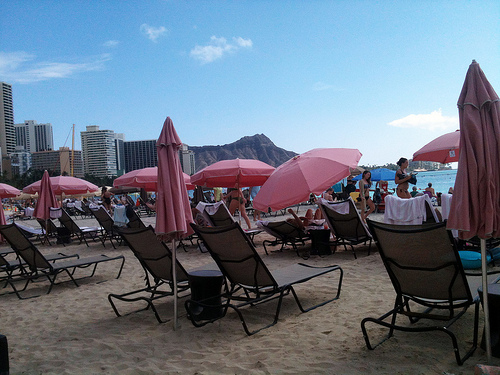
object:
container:
[187, 267, 224, 322]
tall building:
[77, 123, 124, 183]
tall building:
[124, 138, 161, 175]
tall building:
[178, 140, 197, 180]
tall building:
[0, 82, 16, 163]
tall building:
[14, 117, 54, 157]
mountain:
[187, 120, 298, 173]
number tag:
[446, 149, 456, 159]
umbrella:
[409, 125, 467, 165]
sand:
[0, 200, 500, 372]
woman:
[393, 156, 419, 200]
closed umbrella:
[443, 57, 498, 363]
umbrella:
[251, 146, 363, 214]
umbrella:
[151, 115, 201, 337]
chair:
[102, 222, 232, 329]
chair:
[358, 211, 492, 367]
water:
[339, 168, 463, 196]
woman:
[357, 169, 377, 223]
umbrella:
[29, 167, 61, 236]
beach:
[0, 197, 499, 374]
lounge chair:
[191, 219, 345, 335]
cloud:
[185, 29, 258, 66]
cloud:
[133, 19, 171, 43]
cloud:
[0, 39, 123, 84]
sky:
[2, 2, 483, 167]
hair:
[395, 157, 407, 166]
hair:
[361, 169, 374, 186]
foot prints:
[242, 332, 311, 364]